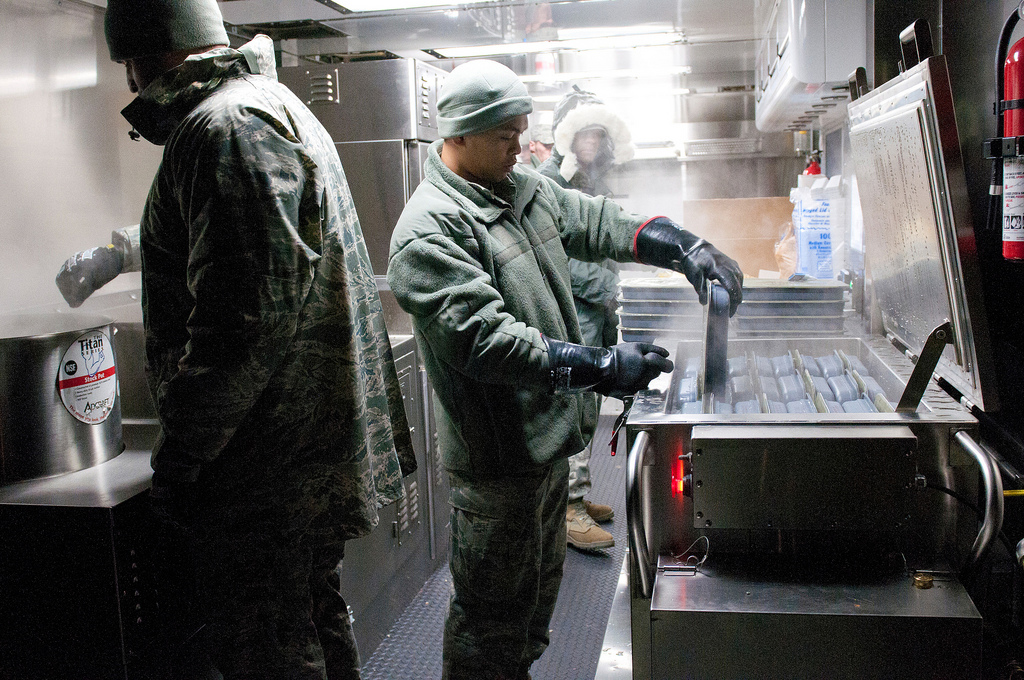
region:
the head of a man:
[447, 72, 530, 187]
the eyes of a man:
[482, 134, 518, 148]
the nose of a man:
[495, 134, 527, 157]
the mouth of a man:
[497, 148, 517, 174]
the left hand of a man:
[649, 214, 739, 301]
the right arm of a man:
[386, 219, 653, 401]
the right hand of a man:
[561, 327, 651, 403]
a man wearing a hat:
[433, 57, 533, 137]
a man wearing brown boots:
[553, 493, 618, 573]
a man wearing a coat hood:
[554, 99, 630, 175]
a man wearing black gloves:
[550, 333, 672, 397]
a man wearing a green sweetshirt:
[406, 181, 618, 485]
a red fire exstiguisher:
[989, 32, 1018, 264]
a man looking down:
[481, 79, 533, 196]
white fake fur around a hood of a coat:
[554, 90, 640, 170]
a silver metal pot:
[4, 320, 115, 479]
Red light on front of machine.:
[658, 411, 684, 545]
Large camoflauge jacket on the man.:
[102, 69, 438, 560]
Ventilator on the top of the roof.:
[228, 7, 350, 50]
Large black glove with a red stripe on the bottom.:
[552, 180, 742, 402]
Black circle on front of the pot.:
[58, 350, 84, 370]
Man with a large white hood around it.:
[538, 72, 637, 189]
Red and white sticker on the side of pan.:
[35, 315, 137, 420]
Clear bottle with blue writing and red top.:
[792, 160, 838, 279]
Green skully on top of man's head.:
[409, 34, 528, 145]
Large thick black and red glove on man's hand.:
[631, 201, 748, 294]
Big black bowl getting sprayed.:
[684, 250, 751, 399]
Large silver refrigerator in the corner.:
[301, 37, 441, 180]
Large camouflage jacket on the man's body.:
[111, 48, 380, 562]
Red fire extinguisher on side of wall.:
[971, 19, 1009, 255]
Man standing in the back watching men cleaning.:
[547, 78, 625, 560]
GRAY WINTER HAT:
[425, 52, 531, 150]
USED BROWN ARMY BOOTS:
[545, 482, 621, 562]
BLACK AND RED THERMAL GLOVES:
[618, 213, 754, 312]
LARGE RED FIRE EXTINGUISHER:
[982, 20, 1021, 262]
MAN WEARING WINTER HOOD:
[545, 84, 648, 192]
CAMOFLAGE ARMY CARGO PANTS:
[428, 416, 578, 677]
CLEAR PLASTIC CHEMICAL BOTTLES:
[789, 160, 854, 277]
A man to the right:
[394, 158, 794, 670]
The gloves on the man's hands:
[562, 203, 744, 419]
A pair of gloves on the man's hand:
[545, 193, 751, 434]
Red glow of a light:
[655, 434, 704, 507]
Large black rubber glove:
[527, 326, 683, 399]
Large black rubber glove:
[619, 202, 753, 317]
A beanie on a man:
[429, 45, 543, 143]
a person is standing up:
[408, 43, 731, 657]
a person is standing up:
[52, 5, 432, 676]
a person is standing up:
[554, 105, 628, 565]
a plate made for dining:
[702, 283, 737, 414]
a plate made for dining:
[756, 377, 798, 434]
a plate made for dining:
[780, 377, 809, 416]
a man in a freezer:
[435, 39, 759, 498]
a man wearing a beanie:
[93, 4, 408, 671]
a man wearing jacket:
[43, 51, 405, 674]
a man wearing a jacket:
[435, 63, 748, 653]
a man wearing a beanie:
[409, 25, 561, 226]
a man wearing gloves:
[435, 86, 865, 674]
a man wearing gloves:
[488, 253, 742, 451]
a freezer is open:
[719, 159, 1014, 600]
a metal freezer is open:
[702, 189, 988, 478]